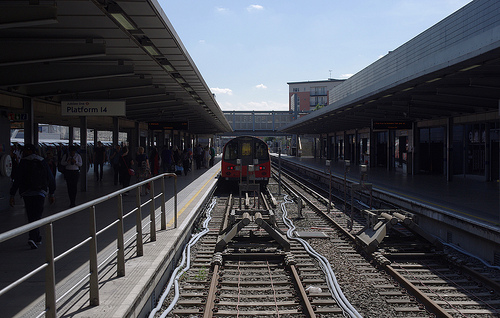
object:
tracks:
[202, 190, 314, 317]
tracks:
[270, 166, 500, 317]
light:
[228, 164, 233, 169]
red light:
[257, 165, 262, 170]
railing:
[0, 172, 179, 243]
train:
[219, 135, 273, 196]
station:
[276, 0, 500, 229]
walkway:
[278, 47, 500, 228]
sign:
[61, 99, 128, 116]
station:
[0, 0, 233, 317]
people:
[10, 145, 56, 250]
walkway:
[0, 1, 233, 318]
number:
[101, 107, 110, 114]